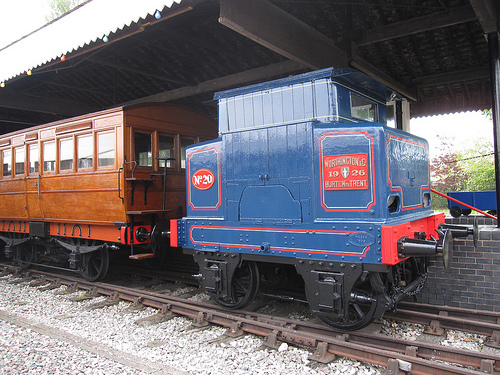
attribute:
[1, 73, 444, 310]
train cars — blue, brown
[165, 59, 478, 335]
car — blue, red, train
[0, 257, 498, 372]
railroad tracks — metal, heavy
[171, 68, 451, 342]
car — train, large, metal, blue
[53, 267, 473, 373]
track — train, rusty, long, large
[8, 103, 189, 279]
train — long, brown, metal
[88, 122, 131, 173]
window — large, square, glass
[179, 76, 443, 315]
car — blue, train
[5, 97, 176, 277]
car — train, orange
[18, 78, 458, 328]
cars — connected, railroad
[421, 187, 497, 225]
object — blue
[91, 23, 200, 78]
roof — tin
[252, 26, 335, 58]
beams — steel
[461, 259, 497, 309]
wall — grey, brick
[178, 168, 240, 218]
sign — red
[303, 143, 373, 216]
sign — red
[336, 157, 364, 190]
text — white